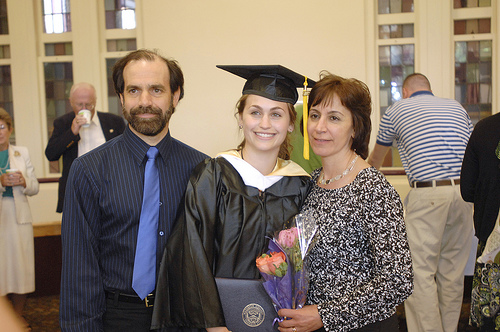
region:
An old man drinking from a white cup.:
[45, 76, 124, 216]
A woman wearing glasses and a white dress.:
[0, 93, 46, 306]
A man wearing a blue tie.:
[52, 41, 221, 330]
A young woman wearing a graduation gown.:
[157, 53, 328, 330]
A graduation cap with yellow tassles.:
[197, 52, 327, 184]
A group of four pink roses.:
[249, 211, 319, 323]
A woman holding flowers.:
[257, 63, 412, 330]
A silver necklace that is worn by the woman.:
[298, 148, 390, 202]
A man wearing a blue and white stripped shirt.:
[355, 66, 479, 328]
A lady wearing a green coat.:
[457, 93, 498, 329]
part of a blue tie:
[125, 237, 157, 272]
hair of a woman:
[343, 97, 368, 156]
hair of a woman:
[171, 63, 183, 78]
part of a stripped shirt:
[397, 119, 434, 173]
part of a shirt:
[73, 269, 97, 302]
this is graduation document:
[218, 278, 271, 329]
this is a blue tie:
[143, 145, 158, 243]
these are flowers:
[259, 228, 308, 303]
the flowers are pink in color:
[253, 225, 306, 280]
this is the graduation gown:
[161, 152, 283, 325]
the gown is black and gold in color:
[176, 158, 300, 320]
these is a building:
[174, 3, 480, 70]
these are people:
[8, 111, 493, 311]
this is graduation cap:
[216, 60, 315, 95]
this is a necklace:
[0, 152, 13, 172]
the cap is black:
[217, 40, 314, 109]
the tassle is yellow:
[295, 77, 322, 162]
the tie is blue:
[120, 132, 177, 302]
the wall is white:
[177, 13, 252, 47]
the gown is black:
[169, 128, 308, 325]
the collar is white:
[212, 141, 295, 198]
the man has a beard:
[110, 42, 190, 149]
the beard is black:
[126, 102, 172, 130]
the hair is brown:
[307, 65, 377, 160]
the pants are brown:
[404, 170, 481, 330]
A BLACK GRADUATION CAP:
[217, 57, 324, 165]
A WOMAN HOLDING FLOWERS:
[246, 66, 416, 330]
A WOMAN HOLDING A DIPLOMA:
[150, 56, 330, 330]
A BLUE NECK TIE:
[127, 140, 167, 306]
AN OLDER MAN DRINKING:
[36, 78, 132, 213]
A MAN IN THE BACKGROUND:
[373, 68, 498, 325]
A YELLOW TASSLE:
[289, 73, 331, 170]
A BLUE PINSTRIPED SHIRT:
[41, 122, 208, 327]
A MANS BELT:
[406, 171, 464, 196]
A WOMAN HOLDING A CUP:
[0, 100, 45, 300]